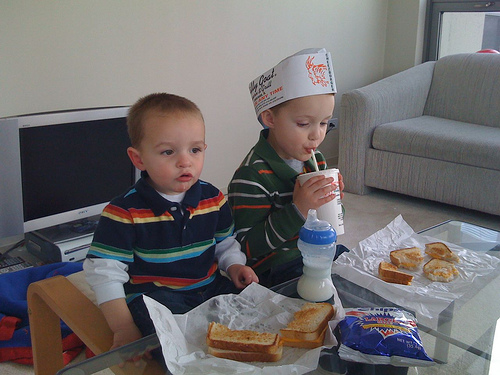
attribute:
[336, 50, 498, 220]
edge of chair — gray, white, grey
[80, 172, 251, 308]
part of shirt — colorful, striped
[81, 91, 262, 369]
child — little, seated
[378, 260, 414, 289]
sandwich — cut up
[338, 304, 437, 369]
bag of potato chips — blue, white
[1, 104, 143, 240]
television — silver, turned off, a flat screen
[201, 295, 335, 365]
sandwich — cut in half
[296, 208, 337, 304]
sippy cup — plastic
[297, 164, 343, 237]
cup — made of paper, white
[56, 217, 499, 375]
coffee table — made of glass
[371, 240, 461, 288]
bites of sandwich — cut into four pieces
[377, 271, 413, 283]
cheese — is grilled